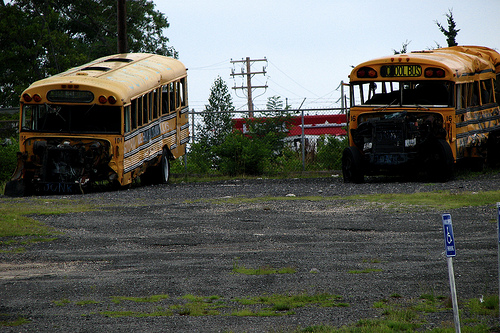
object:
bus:
[340, 45, 500, 186]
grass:
[403, 185, 433, 215]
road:
[0, 172, 500, 333]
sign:
[434, 214, 459, 259]